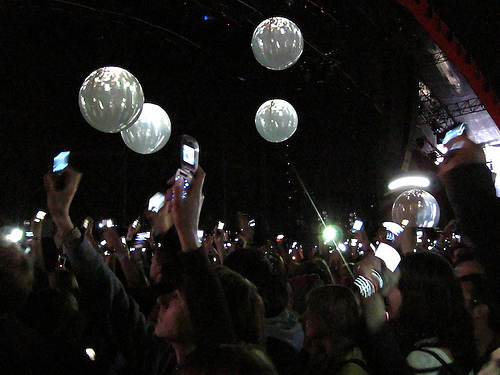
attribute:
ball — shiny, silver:
[71, 59, 148, 140]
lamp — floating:
[247, 9, 309, 77]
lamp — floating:
[257, 96, 299, 151]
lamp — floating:
[74, 54, 145, 144]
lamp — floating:
[118, 100, 176, 164]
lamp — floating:
[385, 189, 440, 250]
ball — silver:
[79, 62, 144, 133]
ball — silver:
[116, 102, 173, 157]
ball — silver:
[389, 185, 442, 232]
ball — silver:
[253, 96, 297, 145]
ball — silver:
[251, 15, 305, 70]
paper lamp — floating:
[118, 101, 172, 156]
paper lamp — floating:
[79, 66, 145, 133]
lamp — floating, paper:
[252, 17, 307, 70]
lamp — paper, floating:
[78, 65, 145, 135]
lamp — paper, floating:
[122, 100, 174, 153]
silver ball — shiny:
[388, 187, 440, 227]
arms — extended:
[38, 163, 235, 253]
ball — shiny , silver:
[235, 91, 306, 129]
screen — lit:
[53, 147, 71, 169]